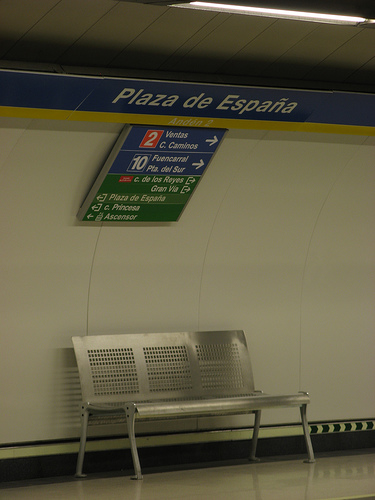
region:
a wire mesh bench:
[68, 325, 316, 473]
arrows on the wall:
[309, 418, 374, 435]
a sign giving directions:
[75, 125, 222, 244]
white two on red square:
[138, 126, 166, 150]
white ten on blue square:
[130, 151, 150, 172]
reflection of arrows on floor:
[208, 465, 374, 480]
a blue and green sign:
[76, 117, 234, 233]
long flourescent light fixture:
[161, 0, 371, 41]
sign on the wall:
[104, 78, 311, 127]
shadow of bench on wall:
[30, 334, 115, 435]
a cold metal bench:
[65, 318, 328, 479]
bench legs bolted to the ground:
[240, 421, 331, 468]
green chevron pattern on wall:
[296, 412, 373, 440]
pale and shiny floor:
[22, 462, 358, 495]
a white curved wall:
[46, 89, 363, 416]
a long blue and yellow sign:
[53, 53, 373, 147]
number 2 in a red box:
[130, 124, 163, 150]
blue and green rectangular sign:
[100, 115, 221, 244]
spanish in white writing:
[108, 81, 299, 116]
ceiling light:
[177, 0, 372, 34]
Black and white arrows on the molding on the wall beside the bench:
[304, 418, 374, 435]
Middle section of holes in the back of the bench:
[139, 341, 200, 391]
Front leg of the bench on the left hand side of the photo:
[121, 401, 144, 483]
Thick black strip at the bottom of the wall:
[4, 461, 127, 483]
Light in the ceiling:
[171, 4, 363, 36]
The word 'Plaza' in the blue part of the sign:
[109, 87, 176, 108]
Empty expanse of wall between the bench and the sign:
[17, 231, 307, 326]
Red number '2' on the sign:
[139, 127, 164, 148]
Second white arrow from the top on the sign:
[188, 156, 206, 172]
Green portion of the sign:
[81, 174, 200, 222]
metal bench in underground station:
[66, 320, 315, 489]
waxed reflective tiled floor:
[6, 451, 372, 499]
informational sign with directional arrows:
[72, 122, 221, 233]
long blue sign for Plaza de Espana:
[2, 80, 374, 119]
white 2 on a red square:
[140, 129, 161, 148]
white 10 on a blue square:
[129, 154, 150, 170]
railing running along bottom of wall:
[0, 419, 373, 462]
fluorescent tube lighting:
[159, 2, 374, 29]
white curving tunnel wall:
[1, 139, 372, 447]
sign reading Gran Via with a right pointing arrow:
[144, 184, 193, 195]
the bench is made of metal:
[65, 324, 317, 484]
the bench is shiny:
[64, 323, 319, 479]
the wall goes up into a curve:
[0, 72, 370, 481]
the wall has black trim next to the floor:
[0, 414, 370, 483]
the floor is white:
[5, 442, 369, 495]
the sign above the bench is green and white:
[68, 120, 224, 232]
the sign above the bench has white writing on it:
[75, 124, 220, 221]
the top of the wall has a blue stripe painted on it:
[0, 68, 373, 126]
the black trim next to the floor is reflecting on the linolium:
[210, 451, 372, 481]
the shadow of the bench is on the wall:
[51, 344, 138, 429]